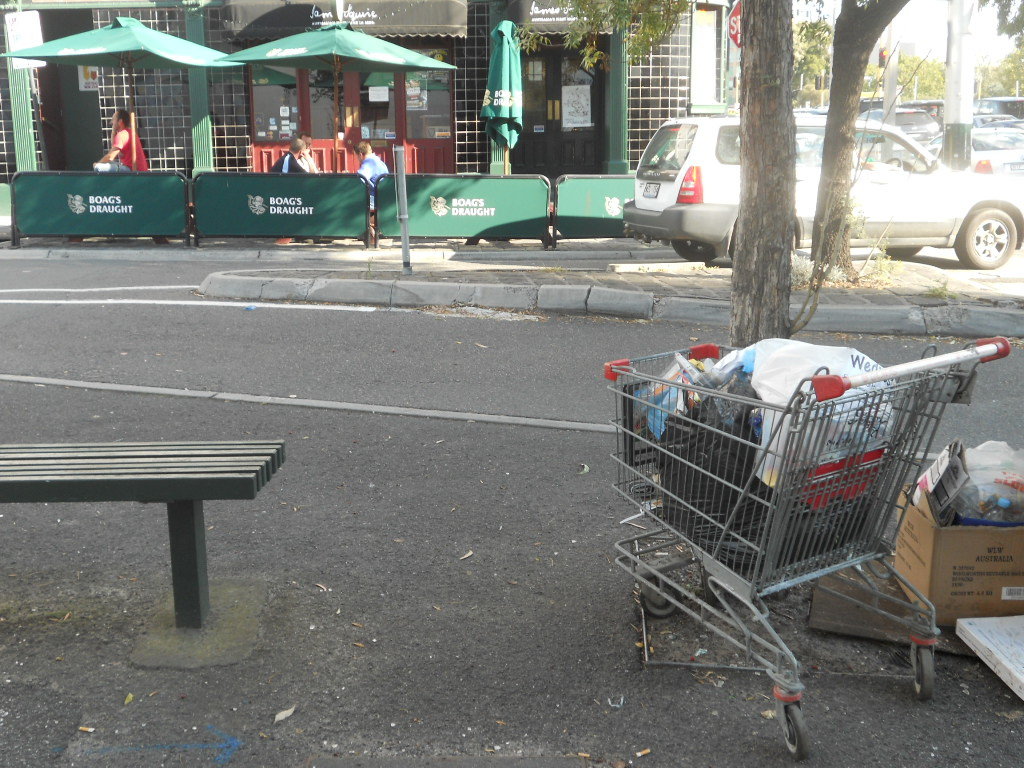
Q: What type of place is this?
A: It is a street.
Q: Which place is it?
A: It is a street.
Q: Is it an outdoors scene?
A: Yes, it is outdoors.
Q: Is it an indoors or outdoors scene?
A: It is outdoors.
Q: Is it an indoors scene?
A: No, it is outdoors.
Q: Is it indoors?
A: No, it is outdoors.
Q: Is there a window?
A: Yes, there is a window.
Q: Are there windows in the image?
A: Yes, there is a window.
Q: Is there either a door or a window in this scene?
A: Yes, there is a window.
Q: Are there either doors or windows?
A: Yes, there is a window.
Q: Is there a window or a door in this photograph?
A: Yes, there is a window.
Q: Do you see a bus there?
A: No, there are no buses.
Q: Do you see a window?
A: Yes, there is a window.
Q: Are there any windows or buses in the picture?
A: Yes, there is a window.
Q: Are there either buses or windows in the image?
A: Yes, there is a window.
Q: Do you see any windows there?
A: Yes, there is a window.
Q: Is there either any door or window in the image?
A: Yes, there is a window.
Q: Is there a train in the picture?
A: No, there are no trains.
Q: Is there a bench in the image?
A: Yes, there is a bench.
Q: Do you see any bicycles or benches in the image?
A: Yes, there is a bench.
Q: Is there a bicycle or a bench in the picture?
A: Yes, there is a bench.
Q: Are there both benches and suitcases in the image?
A: No, there is a bench but no suitcases.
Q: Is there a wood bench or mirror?
A: Yes, there is a wood bench.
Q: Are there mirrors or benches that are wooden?
A: Yes, the bench is wooden.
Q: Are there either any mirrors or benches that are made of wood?
A: Yes, the bench is made of wood.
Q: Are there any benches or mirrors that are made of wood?
A: Yes, the bench is made of wood.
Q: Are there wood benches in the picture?
A: Yes, there is a wood bench.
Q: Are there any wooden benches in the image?
A: Yes, there is a wood bench.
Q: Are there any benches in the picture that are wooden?
A: Yes, there is a bench that is wooden.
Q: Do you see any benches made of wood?
A: Yes, there is a bench that is made of wood.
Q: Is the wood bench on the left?
A: Yes, the bench is on the left of the image.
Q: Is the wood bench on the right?
A: No, the bench is on the left of the image.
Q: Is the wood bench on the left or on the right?
A: The bench is on the left of the image.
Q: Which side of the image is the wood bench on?
A: The bench is on the left of the image.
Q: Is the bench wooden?
A: Yes, the bench is wooden.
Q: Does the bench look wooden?
A: Yes, the bench is wooden.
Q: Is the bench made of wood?
A: Yes, the bench is made of wood.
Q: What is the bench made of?
A: The bench is made of wood.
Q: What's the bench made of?
A: The bench is made of wood.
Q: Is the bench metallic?
A: No, the bench is wooden.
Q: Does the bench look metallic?
A: No, the bench is wooden.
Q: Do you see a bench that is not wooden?
A: No, there is a bench but it is wooden.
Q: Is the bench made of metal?
A: No, the bench is made of wood.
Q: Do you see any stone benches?
A: No, there is a bench but it is made of wood.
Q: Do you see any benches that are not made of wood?
A: No, there is a bench but it is made of wood.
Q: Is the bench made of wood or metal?
A: The bench is made of wood.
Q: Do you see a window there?
A: Yes, there is a window.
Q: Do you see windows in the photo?
A: Yes, there is a window.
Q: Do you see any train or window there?
A: Yes, there is a window.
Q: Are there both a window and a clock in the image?
A: No, there is a window but no clocks.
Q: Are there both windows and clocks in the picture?
A: No, there is a window but no clocks.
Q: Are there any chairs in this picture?
A: No, there are no chairs.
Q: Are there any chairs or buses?
A: No, there are no chairs or buses.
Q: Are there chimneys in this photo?
A: No, there are no chimneys.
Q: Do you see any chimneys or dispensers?
A: No, there are no chimneys or dispensers.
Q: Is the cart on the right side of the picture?
A: Yes, the cart is on the right of the image.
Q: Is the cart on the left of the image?
A: No, the cart is on the right of the image.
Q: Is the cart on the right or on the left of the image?
A: The cart is on the right of the image.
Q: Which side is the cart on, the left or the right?
A: The cart is on the right of the image.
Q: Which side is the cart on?
A: The cart is on the right of the image.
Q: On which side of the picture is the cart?
A: The cart is on the right of the image.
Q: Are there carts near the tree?
A: Yes, there is a cart near the tree.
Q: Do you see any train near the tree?
A: No, there is a cart near the tree.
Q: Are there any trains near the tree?
A: No, there is a cart near the tree.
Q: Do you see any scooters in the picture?
A: No, there are no scooters.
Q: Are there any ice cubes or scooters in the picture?
A: No, there are no scooters or ice cubes.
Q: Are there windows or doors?
A: Yes, there is a window.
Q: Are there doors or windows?
A: Yes, there is a window.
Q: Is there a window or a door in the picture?
A: Yes, there is a window.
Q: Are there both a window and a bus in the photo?
A: No, there is a window but no buses.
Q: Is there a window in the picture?
A: Yes, there is a window.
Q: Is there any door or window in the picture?
A: Yes, there is a window.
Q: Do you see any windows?
A: Yes, there is a window.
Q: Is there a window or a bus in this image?
A: Yes, there is a window.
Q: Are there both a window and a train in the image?
A: No, there is a window but no trains.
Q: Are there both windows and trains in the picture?
A: No, there is a window but no trains.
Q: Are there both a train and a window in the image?
A: No, there is a window but no trains.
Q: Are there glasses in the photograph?
A: No, there are no glasses.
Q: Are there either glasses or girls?
A: No, there are no glasses or girls.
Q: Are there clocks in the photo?
A: No, there are no clocks.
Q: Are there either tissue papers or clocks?
A: No, there are no clocks or tissue papers.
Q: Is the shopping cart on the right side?
A: Yes, the shopping cart is on the right of the image.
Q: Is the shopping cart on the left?
A: No, the shopping cart is on the right of the image.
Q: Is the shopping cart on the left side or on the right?
A: The shopping cart is on the right of the image.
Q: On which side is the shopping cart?
A: The shopping cart is on the right of the image.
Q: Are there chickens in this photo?
A: No, there are no chickens.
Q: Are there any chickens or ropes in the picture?
A: No, there are no chickens or ropes.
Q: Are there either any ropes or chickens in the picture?
A: No, there are no chickens or ropes.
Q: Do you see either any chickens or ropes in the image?
A: No, there are no chickens or ropes.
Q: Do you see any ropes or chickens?
A: No, there are no chickens or ropes.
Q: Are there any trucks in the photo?
A: No, there are no trucks.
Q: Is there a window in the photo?
A: Yes, there is a window.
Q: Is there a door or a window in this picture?
A: Yes, there is a window.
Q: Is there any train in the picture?
A: No, there are no trains.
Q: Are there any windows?
A: Yes, there is a window.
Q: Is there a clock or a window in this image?
A: Yes, there is a window.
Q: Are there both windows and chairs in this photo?
A: No, there is a window but no chairs.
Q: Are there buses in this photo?
A: No, there are no buses.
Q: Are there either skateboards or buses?
A: No, there are no buses or skateboards.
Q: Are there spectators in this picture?
A: No, there are no spectators.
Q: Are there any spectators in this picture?
A: No, there are no spectators.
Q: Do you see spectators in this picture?
A: No, there are no spectators.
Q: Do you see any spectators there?
A: No, there are no spectators.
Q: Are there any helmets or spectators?
A: No, there are no spectators or helmets.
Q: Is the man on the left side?
A: Yes, the man is on the left of the image.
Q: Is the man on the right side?
A: No, the man is on the left of the image.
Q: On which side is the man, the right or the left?
A: The man is on the left of the image.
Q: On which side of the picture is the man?
A: The man is on the left of the image.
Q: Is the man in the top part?
A: Yes, the man is in the top of the image.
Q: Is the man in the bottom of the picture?
A: No, the man is in the top of the image.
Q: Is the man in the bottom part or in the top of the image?
A: The man is in the top of the image.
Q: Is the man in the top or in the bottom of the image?
A: The man is in the top of the image.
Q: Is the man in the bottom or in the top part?
A: The man is in the top of the image.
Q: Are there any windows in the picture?
A: Yes, there is a window.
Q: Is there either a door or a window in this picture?
A: Yes, there is a window.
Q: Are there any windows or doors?
A: Yes, there is a window.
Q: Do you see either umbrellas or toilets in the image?
A: Yes, there is an umbrella.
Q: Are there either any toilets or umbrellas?
A: Yes, there is an umbrella.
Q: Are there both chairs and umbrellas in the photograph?
A: No, there is an umbrella but no chairs.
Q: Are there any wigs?
A: No, there are no wigs.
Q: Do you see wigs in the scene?
A: No, there are no wigs.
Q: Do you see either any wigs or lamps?
A: No, there are no wigs or lamps.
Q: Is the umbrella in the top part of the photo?
A: Yes, the umbrella is in the top of the image.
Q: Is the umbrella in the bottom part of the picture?
A: No, the umbrella is in the top of the image.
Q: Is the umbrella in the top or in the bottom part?
A: The umbrella is in the top of the image.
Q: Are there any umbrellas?
A: Yes, there is an umbrella.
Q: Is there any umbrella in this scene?
A: Yes, there is an umbrella.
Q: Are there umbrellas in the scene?
A: Yes, there is an umbrella.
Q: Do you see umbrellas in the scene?
A: Yes, there is an umbrella.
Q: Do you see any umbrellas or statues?
A: Yes, there is an umbrella.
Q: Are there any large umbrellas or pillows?
A: Yes, there is a large umbrella.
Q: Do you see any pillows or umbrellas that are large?
A: Yes, the umbrella is large.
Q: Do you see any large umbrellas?
A: Yes, there is a large umbrella.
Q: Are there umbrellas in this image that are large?
A: Yes, there is an umbrella that is large.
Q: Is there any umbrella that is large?
A: Yes, there is an umbrella that is large.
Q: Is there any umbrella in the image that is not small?
A: Yes, there is a large umbrella.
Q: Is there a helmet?
A: No, there are no helmets.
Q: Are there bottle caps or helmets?
A: No, there are no helmets or bottle caps.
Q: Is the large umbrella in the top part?
A: Yes, the umbrella is in the top of the image.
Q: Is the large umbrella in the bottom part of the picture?
A: No, the umbrella is in the top of the image.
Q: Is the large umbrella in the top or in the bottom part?
A: The umbrella is in the top of the image.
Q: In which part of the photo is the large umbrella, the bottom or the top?
A: The umbrella is in the top of the image.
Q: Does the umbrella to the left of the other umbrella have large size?
A: Yes, the umbrella is large.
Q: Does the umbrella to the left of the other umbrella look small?
A: No, the umbrella is large.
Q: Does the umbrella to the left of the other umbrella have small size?
A: No, the umbrella is large.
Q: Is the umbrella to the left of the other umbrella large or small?
A: The umbrella is large.